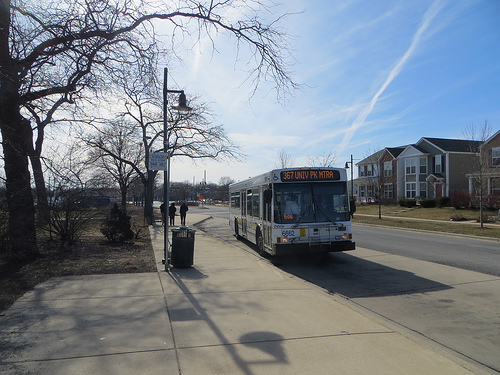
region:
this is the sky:
[344, 17, 479, 130]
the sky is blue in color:
[363, 56, 399, 103]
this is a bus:
[251, 166, 360, 258]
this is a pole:
[159, 64, 181, 239]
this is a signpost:
[145, 147, 168, 167]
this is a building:
[392, 144, 447, 188]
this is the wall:
[450, 160, 467, 190]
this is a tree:
[463, 135, 493, 219]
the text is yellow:
[282, 168, 334, 178]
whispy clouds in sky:
[186, 0, 498, 157]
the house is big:
[395, 138, 485, 203]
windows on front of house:
[405, 165, 426, 200]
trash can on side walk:
[172, 226, 194, 267]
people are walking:
[160, 201, 187, 224]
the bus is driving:
[228, 166, 356, 263]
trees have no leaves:
[2, 0, 303, 270]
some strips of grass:
[350, 203, 499, 242]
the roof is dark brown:
[423, 136, 487, 153]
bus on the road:
[217, 157, 367, 274]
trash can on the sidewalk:
[169, 218, 205, 275]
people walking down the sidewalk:
[154, 191, 199, 231]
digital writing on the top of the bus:
[277, 166, 340, 185]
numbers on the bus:
[276, 228, 300, 238]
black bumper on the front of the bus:
[275, 240, 360, 256]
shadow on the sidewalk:
[166, 265, 299, 374]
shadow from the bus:
[290, 254, 452, 311]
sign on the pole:
[145, 147, 170, 175]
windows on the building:
[401, 159, 428, 198]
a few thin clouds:
[289, 0, 408, 147]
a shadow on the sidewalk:
[162, 263, 294, 368]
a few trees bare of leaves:
[84, 94, 224, 236]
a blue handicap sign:
[268, 170, 281, 187]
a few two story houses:
[348, 132, 495, 214]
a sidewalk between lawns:
[366, 200, 484, 230]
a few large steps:
[383, 200, 418, 216]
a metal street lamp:
[165, 88, 196, 115]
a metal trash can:
[163, 220, 197, 271]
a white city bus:
[225, 166, 360, 264]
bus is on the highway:
[252, 164, 378, 277]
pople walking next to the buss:
[155, 187, 208, 224]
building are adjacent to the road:
[341, 139, 494, 211]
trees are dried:
[63, 31, 150, 100]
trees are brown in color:
[56, 34, 173, 112]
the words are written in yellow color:
[286, 169, 345, 181]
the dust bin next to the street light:
[176, 215, 209, 264]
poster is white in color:
[146, 150, 172, 175]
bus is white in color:
[231, 174, 341, 237]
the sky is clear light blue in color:
[430, 59, 479, 97]